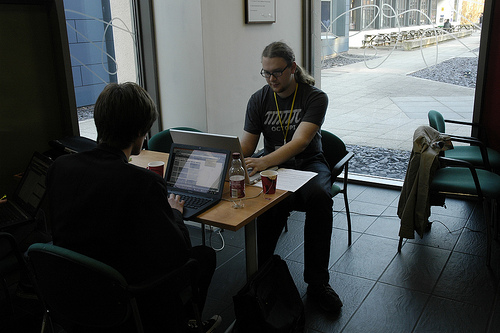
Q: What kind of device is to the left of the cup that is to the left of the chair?
A: The device is a screen.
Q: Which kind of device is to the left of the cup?
A: The device is a screen.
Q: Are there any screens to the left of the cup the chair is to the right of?
A: Yes, there is a screen to the left of the cup.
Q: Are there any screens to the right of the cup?
A: No, the screen is to the left of the cup.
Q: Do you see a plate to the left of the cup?
A: No, there is a screen to the left of the cup.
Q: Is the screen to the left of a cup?
A: Yes, the screen is to the left of a cup.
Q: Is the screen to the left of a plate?
A: No, the screen is to the left of a cup.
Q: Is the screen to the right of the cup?
A: No, the screen is to the left of the cup.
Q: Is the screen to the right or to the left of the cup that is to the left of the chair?
A: The screen is to the left of the cup.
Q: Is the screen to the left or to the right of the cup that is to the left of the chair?
A: The screen is to the left of the cup.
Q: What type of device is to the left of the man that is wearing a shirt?
A: The device is a screen.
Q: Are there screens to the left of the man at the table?
A: Yes, there is a screen to the left of the man.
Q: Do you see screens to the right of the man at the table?
A: No, the screen is to the left of the man.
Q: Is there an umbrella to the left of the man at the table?
A: No, there is a screen to the left of the man.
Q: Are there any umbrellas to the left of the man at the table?
A: No, there is a screen to the left of the man.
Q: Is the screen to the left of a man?
A: Yes, the screen is to the left of a man.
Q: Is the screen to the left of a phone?
A: No, the screen is to the left of a man.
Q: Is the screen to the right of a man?
A: No, the screen is to the left of a man.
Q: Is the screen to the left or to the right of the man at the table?
A: The screen is to the left of the man.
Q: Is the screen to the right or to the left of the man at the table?
A: The screen is to the left of the man.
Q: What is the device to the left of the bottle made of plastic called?
A: The device is a screen.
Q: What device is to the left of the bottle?
A: The device is a screen.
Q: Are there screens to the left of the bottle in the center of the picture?
A: Yes, there is a screen to the left of the bottle.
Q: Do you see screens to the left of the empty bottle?
A: Yes, there is a screen to the left of the bottle.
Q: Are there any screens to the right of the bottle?
A: No, the screen is to the left of the bottle.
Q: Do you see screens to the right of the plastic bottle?
A: No, the screen is to the left of the bottle.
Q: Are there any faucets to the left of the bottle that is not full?
A: No, there is a screen to the left of the bottle.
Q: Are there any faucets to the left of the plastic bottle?
A: No, there is a screen to the left of the bottle.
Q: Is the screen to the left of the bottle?
A: Yes, the screen is to the left of the bottle.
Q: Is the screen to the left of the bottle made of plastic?
A: Yes, the screen is to the left of the bottle.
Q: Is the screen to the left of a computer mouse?
A: No, the screen is to the left of the bottle.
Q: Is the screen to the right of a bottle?
A: No, the screen is to the left of a bottle.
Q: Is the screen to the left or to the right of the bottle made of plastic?
A: The screen is to the left of the bottle.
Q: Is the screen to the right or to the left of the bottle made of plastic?
A: The screen is to the left of the bottle.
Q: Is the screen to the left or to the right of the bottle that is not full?
A: The screen is to the left of the bottle.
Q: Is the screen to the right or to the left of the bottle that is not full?
A: The screen is to the left of the bottle.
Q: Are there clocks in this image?
A: No, there are no clocks.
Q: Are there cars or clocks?
A: No, there are no clocks or cars.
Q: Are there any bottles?
A: Yes, there is a bottle.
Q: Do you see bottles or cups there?
A: Yes, there is a bottle.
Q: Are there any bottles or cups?
A: Yes, there is a bottle.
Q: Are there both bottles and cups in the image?
A: Yes, there are both a bottle and a cup.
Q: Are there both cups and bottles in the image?
A: Yes, there are both a bottle and a cup.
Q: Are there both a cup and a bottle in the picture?
A: Yes, there are both a bottle and a cup.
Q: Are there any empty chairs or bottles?
A: Yes, there is an empty bottle.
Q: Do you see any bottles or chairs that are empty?
A: Yes, the bottle is empty.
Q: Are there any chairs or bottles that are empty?
A: Yes, the bottle is empty.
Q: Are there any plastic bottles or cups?
A: Yes, there is a plastic bottle.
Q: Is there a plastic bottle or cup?
A: Yes, there is a plastic bottle.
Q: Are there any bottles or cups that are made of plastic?
A: Yes, the bottle is made of plastic.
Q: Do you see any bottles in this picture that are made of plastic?
A: Yes, there is a bottle that is made of plastic.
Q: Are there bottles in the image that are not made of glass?
A: Yes, there is a bottle that is made of plastic.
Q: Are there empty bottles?
A: Yes, there is an empty bottle.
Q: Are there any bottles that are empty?
A: Yes, there is a bottle that is empty.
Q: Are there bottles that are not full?
A: Yes, there is a empty bottle.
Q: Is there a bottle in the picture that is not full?
A: Yes, there is a empty bottle.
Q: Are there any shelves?
A: No, there are no shelves.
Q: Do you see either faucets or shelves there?
A: No, there are no shelves or faucets.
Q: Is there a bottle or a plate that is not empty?
A: No, there is a bottle but it is empty.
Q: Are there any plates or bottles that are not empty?
A: No, there is a bottle but it is empty.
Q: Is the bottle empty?
A: Yes, the bottle is empty.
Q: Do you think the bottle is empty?
A: Yes, the bottle is empty.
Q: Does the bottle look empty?
A: Yes, the bottle is empty.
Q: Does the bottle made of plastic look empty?
A: Yes, the bottle is empty.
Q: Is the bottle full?
A: No, the bottle is empty.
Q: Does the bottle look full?
A: No, the bottle is empty.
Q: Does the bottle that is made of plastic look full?
A: No, the bottle is empty.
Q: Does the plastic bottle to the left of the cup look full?
A: No, the bottle is empty.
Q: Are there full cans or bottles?
A: No, there is a bottle but it is empty.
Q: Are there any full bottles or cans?
A: No, there is a bottle but it is empty.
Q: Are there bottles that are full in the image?
A: No, there is a bottle but it is empty.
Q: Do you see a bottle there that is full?
A: No, there is a bottle but it is empty.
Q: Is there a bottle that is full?
A: No, there is a bottle but it is empty.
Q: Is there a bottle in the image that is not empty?
A: No, there is a bottle but it is empty.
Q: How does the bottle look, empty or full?
A: The bottle is empty.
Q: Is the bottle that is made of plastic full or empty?
A: The bottle is empty.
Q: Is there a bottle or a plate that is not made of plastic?
A: No, there is a bottle but it is made of plastic.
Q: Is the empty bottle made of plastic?
A: Yes, the bottle is made of plastic.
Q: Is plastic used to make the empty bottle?
A: Yes, the bottle is made of plastic.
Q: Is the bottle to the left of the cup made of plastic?
A: Yes, the bottle is made of plastic.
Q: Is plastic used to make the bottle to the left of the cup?
A: Yes, the bottle is made of plastic.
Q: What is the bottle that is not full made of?
A: The bottle is made of plastic.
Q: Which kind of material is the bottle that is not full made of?
A: The bottle is made of plastic.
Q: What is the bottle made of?
A: The bottle is made of plastic.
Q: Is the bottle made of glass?
A: No, the bottle is made of plastic.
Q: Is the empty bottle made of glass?
A: No, the bottle is made of plastic.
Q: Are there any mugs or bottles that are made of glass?
A: No, there is a bottle but it is made of plastic.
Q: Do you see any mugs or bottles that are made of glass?
A: No, there is a bottle but it is made of plastic.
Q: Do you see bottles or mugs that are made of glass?
A: No, there is a bottle but it is made of plastic.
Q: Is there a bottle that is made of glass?
A: No, there is a bottle but it is made of plastic.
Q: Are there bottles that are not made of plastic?
A: No, there is a bottle but it is made of plastic.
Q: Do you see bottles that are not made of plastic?
A: No, there is a bottle but it is made of plastic.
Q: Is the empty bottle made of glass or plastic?
A: The bottle is made of plastic.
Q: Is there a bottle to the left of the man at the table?
A: Yes, there is a bottle to the left of the man.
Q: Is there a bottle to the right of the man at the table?
A: No, the bottle is to the left of the man.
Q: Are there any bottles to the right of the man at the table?
A: No, the bottle is to the left of the man.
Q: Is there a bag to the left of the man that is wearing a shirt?
A: No, there is a bottle to the left of the man.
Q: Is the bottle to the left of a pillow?
A: No, the bottle is to the left of a man.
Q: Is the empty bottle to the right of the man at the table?
A: No, the bottle is to the left of the man.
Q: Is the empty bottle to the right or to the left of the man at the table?
A: The bottle is to the left of the man.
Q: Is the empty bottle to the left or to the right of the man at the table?
A: The bottle is to the left of the man.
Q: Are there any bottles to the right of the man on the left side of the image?
A: Yes, there is a bottle to the right of the man.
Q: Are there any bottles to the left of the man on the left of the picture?
A: No, the bottle is to the right of the man.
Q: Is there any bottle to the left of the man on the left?
A: No, the bottle is to the right of the man.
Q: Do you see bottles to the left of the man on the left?
A: No, the bottle is to the right of the man.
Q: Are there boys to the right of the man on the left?
A: No, there is a bottle to the right of the man.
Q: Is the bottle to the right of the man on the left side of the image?
A: Yes, the bottle is to the right of the man.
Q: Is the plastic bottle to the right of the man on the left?
A: Yes, the bottle is to the right of the man.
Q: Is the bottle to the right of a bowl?
A: No, the bottle is to the right of the man.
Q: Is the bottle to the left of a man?
A: No, the bottle is to the right of a man.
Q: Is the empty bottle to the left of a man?
A: No, the bottle is to the right of a man.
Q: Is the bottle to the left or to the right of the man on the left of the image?
A: The bottle is to the right of the man.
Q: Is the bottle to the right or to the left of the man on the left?
A: The bottle is to the right of the man.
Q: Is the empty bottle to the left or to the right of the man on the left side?
A: The bottle is to the right of the man.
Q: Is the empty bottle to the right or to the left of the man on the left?
A: The bottle is to the right of the man.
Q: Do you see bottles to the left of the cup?
A: Yes, there is a bottle to the left of the cup.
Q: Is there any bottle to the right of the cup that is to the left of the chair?
A: No, the bottle is to the left of the cup.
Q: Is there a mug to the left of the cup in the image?
A: No, there is a bottle to the left of the cup.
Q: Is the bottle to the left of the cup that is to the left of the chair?
A: Yes, the bottle is to the left of the cup.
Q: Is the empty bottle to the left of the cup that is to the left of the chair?
A: Yes, the bottle is to the left of the cup.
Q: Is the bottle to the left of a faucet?
A: No, the bottle is to the left of the cup.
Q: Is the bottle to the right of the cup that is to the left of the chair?
A: No, the bottle is to the left of the cup.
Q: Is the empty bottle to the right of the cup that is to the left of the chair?
A: No, the bottle is to the left of the cup.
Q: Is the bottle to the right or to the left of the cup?
A: The bottle is to the left of the cup.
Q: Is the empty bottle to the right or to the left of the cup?
A: The bottle is to the left of the cup.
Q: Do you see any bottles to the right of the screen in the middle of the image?
A: Yes, there is a bottle to the right of the screen.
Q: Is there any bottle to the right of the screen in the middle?
A: Yes, there is a bottle to the right of the screen.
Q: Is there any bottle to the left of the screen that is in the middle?
A: No, the bottle is to the right of the screen.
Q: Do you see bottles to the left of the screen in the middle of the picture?
A: No, the bottle is to the right of the screen.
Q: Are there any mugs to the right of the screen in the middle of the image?
A: No, there is a bottle to the right of the screen.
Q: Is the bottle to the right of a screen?
A: Yes, the bottle is to the right of a screen.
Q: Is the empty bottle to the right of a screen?
A: Yes, the bottle is to the right of a screen.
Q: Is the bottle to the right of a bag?
A: No, the bottle is to the right of a screen.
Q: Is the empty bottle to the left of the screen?
A: No, the bottle is to the right of the screen.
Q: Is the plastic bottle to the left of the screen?
A: No, the bottle is to the right of the screen.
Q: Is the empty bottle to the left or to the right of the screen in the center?
A: The bottle is to the right of the screen.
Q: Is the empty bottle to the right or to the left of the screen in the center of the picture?
A: The bottle is to the right of the screen.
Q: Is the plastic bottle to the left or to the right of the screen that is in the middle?
A: The bottle is to the right of the screen.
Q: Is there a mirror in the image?
A: No, there are no mirrors.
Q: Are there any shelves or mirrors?
A: No, there are no mirrors or shelves.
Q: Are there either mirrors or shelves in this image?
A: No, there are no mirrors or shelves.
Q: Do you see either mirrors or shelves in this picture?
A: No, there are no mirrors or shelves.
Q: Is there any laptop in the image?
A: Yes, there is a laptop.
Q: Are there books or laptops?
A: Yes, there is a laptop.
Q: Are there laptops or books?
A: Yes, there is a laptop.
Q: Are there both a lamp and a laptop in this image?
A: No, there is a laptop but no lamps.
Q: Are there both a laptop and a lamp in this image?
A: No, there is a laptop but no lamps.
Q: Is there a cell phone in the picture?
A: No, there are no cell phones.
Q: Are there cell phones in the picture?
A: No, there are no cell phones.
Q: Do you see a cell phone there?
A: No, there are no cell phones.